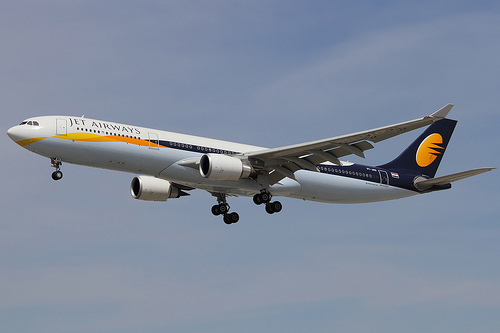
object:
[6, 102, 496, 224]
airplane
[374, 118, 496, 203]
tail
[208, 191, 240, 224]
landing gear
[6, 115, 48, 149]
cockpit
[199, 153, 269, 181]
engine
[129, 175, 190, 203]
engine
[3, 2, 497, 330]
sky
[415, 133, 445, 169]
logo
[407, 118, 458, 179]
background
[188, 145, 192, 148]
windows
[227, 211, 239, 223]
wheels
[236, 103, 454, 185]
wing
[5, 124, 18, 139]
tip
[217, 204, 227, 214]
tire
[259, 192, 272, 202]
tire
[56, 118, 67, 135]
door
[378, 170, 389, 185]
door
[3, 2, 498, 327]
clouds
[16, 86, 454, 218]
passengers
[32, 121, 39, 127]
windows